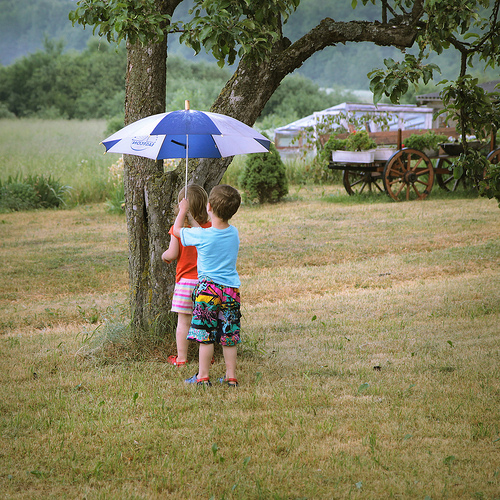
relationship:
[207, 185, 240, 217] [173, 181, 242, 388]
head of boy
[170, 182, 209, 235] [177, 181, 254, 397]
head of person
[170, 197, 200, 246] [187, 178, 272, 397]
arm of person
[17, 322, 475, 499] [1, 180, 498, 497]
ground covered in grass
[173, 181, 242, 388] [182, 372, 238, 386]
boy wearing sandles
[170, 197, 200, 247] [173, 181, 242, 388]
arm of boy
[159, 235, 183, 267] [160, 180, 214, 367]
arm of person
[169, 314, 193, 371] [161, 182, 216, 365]
leg of girl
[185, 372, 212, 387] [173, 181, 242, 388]
feet on boy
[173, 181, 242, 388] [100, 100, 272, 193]
boy holding an umbrella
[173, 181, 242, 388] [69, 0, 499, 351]
boy next to a tree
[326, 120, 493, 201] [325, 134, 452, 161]
cart with plants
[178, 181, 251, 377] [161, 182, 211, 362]
boy behind girl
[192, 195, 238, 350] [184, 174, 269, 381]
feet of a person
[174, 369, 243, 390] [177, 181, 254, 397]
feet of a person